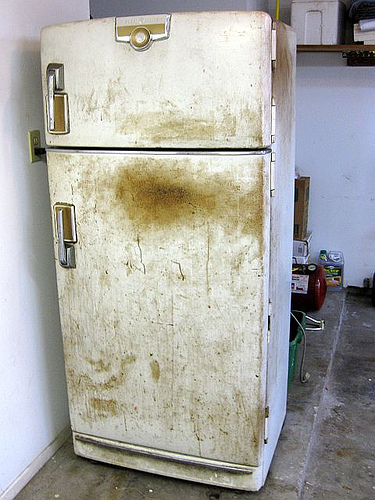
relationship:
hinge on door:
[270, 29, 278, 61] [37, 21, 278, 148]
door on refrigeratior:
[37, 21, 278, 148] [34, 18, 306, 418]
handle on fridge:
[55, 207, 76, 269] [38, 8, 298, 495]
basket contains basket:
[286, 301, 306, 384] [286, 308, 307, 386]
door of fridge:
[38, 8, 272, 150] [38, 8, 298, 495]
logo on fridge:
[115, 13, 171, 51] [38, 8, 298, 495]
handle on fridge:
[44, 61, 71, 137] [38, 8, 298, 495]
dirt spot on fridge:
[113, 165, 266, 240] [40, 8, 298, 492]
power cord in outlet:
[36, 144, 47, 156] [25, 129, 44, 160]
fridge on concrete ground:
[40, 8, 298, 492] [10, 287, 374, 499]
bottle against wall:
[318, 248, 329, 266] [286, 46, 374, 296]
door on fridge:
[43, 145, 264, 475] [38, 8, 298, 495]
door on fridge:
[38, 8, 272, 150] [38, 8, 298, 495]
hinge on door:
[260, 413, 272, 447] [43, 145, 264, 475]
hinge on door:
[264, 297, 272, 344] [43, 145, 264, 475]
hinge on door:
[270, 100, 278, 148] [38, 8, 272, 150]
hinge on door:
[269, 27, 278, 65] [38, 8, 272, 150]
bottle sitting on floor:
[319, 247, 347, 296] [306, 436, 344, 480]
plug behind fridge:
[26, 128, 44, 165] [38, 8, 298, 495]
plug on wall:
[21, 125, 46, 166] [2, 2, 94, 498]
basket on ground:
[286, 308, 307, 386] [325, 346, 372, 446]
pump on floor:
[289, 260, 328, 315] [12, 287, 375, 500]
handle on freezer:
[44, 62, 56, 131] [39, 11, 272, 150]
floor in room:
[286, 303, 371, 498] [3, 1, 374, 497]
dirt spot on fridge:
[113, 156, 265, 247] [38, 8, 298, 495]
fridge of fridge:
[38, 8, 298, 495] [38, 8, 298, 495]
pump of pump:
[289, 243, 320, 281] [289, 260, 328, 315]